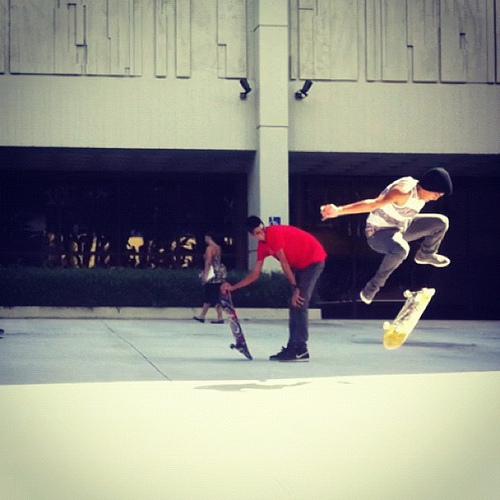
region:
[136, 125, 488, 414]
there are three people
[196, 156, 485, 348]
two men are skating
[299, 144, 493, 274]
this skater has a black hat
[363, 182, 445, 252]
the skater has a striped shirt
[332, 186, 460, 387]
the skateboard is yellow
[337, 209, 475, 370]
both of his feet are in the air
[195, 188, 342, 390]
this skater is bending forward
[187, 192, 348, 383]
his shirt is red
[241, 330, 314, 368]
his shoes are black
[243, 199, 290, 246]
behind him is a handicapped sign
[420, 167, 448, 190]
this is a marvin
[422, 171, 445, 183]
the marvin is black in color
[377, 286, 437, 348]
this is a skateboard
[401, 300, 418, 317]
the skateboard is wooden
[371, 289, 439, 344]
the skateboard is in the air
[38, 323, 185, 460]
this is the ground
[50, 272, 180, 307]
this is a hedge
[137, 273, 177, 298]
the leaves are green in color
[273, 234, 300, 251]
the t-shirt is red in color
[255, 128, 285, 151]
the wall is white in color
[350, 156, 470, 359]
person in the air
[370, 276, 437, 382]
skateboard beneath feet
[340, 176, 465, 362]
person doing a trick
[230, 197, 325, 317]
person in a red shirt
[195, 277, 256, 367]
person with a board in hand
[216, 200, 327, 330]
person looking to left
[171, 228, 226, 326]
lady walking on sidewalk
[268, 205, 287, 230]
handicap sign behind people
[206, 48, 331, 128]
two cameras on wall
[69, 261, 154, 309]
bush next to person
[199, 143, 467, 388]
a man holding a skateboard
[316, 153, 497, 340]
boy is skateboarding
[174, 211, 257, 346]
the woman is walking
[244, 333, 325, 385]
the shoes are black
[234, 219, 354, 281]
the shirt is red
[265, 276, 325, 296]
man is wearing a watch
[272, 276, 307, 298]
the watch is black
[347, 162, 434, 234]
the sleeveless shirt is stripes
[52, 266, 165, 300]
the bushes are green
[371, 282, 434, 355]
A WOODEN SKATEBOARD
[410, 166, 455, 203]
A BLACK HAT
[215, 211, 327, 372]
A PHOTO OF A GUY BENDING OVER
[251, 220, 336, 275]
A RED TEE SHIRT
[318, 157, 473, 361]
A PICTURE OF A GUY JUMPING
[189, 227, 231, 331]
A WOMAN WALKING AWAY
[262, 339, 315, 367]
A PAIR OF SNEAKERS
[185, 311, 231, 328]
A PAIR OF LADIES SHOES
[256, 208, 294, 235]
THE NUMBER 19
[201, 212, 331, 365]
A GUY HOLDING A SKATEBOARD